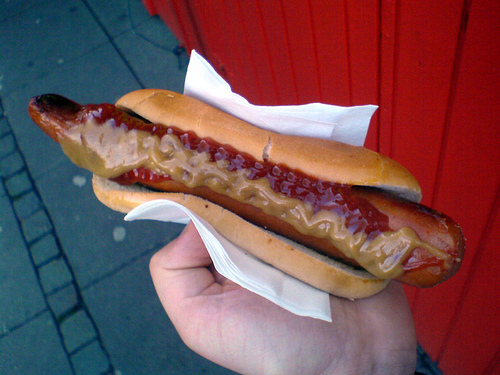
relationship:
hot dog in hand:
[11, 64, 471, 309] [129, 213, 437, 373]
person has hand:
[147, 217, 419, 374] [129, 213, 437, 373]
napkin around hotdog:
[177, 47, 379, 136] [25, 86, 462, 297]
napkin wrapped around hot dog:
[122, 50, 378, 324] [11, 64, 471, 309]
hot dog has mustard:
[11, 64, 471, 309] [59, 125, 418, 275]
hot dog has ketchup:
[11, 64, 471, 309] [75, 99, 379, 228]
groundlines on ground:
[0, 108, 109, 373] [2, 0, 438, 372]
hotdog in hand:
[25, 86, 462, 297] [129, 213, 437, 373]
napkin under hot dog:
[167, 63, 398, 144] [126, 124, 496, 305]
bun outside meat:
[114, 78, 421, 198] [20, 88, 475, 289]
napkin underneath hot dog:
[177, 47, 379, 136] [11, 64, 471, 309]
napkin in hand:
[122, 50, 378, 324] [129, 213, 437, 373]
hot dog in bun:
[11, 64, 471, 309] [87, 77, 422, 303]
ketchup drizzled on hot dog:
[259, 163, 381, 215] [32, 72, 459, 269]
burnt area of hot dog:
[23, 84, 76, 124] [11, 64, 471, 309]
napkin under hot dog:
[177, 47, 379, 136] [106, 80, 449, 292]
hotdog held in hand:
[25, 86, 462, 297] [129, 213, 437, 373]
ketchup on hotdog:
[59, 97, 394, 232] [25, 86, 462, 297]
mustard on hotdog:
[59, 125, 418, 275] [25, 86, 462, 297]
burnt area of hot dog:
[23, 84, 76, 124] [45, 89, 460, 271]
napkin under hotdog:
[122, 50, 378, 324] [25, 86, 462, 297]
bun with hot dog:
[114, 78, 421, 198] [11, 64, 471, 309]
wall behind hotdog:
[232, 4, 492, 138] [25, 86, 462, 297]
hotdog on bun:
[25, 86, 462, 297] [338, 153, 433, 194]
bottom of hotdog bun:
[91, 175, 407, 302] [87, 87, 421, 301]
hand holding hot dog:
[129, 213, 437, 373] [19, 91, 493, 279]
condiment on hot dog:
[189, 166, 277, 209] [184, 99, 451, 290]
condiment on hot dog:
[134, 105, 246, 161] [184, 99, 451, 290]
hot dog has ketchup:
[62, 55, 488, 217] [92, 107, 175, 124]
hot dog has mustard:
[62, 55, 488, 217] [304, 209, 402, 265]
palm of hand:
[170, 257, 423, 363] [129, 213, 437, 373]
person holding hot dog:
[147, 217, 419, 374] [11, 64, 471, 309]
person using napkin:
[147, 217, 419, 374] [122, 50, 378, 324]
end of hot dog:
[343, 155, 452, 310] [11, 64, 471, 309]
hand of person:
[129, 213, 437, 373] [116, 1, 497, 372]